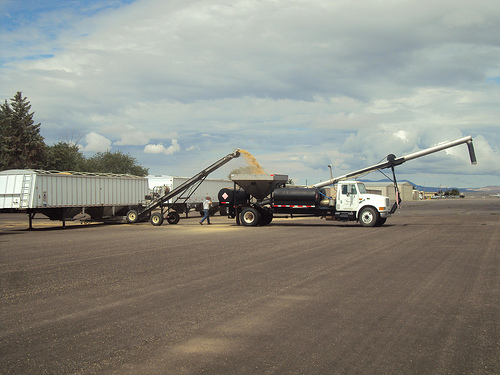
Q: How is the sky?
A: Cloudy.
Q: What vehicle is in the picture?
A: Truck.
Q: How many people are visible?
A: One.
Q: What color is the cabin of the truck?
A: White.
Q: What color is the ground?
A: Brown.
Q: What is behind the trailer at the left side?
A: Trees.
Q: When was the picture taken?
A: During daytime.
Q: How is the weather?
A: Overcast.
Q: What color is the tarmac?
A: Gray.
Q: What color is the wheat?
A: Tan.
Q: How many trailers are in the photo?
A: 2.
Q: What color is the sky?
A: Blue.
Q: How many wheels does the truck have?
A: 4.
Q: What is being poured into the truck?
A: Sand.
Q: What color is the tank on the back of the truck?
A: Black.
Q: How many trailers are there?
A: Two.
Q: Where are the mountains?
A: In the back.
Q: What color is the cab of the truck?
A: White.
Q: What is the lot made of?
A: Asphalt.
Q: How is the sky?
A: Cloudy.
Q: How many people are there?
A: One.